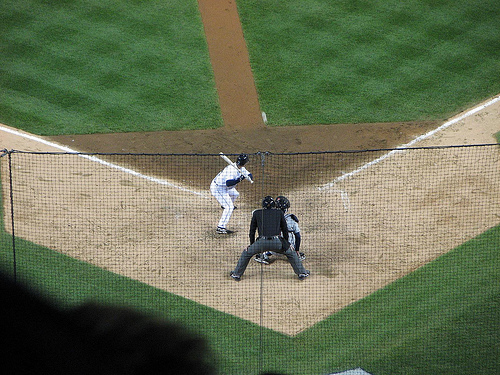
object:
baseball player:
[230, 192, 312, 281]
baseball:
[262, 111, 269, 123]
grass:
[2, 1, 497, 375]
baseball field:
[3, 2, 500, 372]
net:
[2, 147, 499, 372]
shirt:
[215, 160, 250, 184]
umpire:
[231, 194, 311, 282]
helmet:
[236, 152, 251, 164]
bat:
[216, 152, 255, 185]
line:
[2, 124, 204, 203]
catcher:
[256, 195, 307, 262]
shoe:
[216, 225, 228, 236]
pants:
[233, 239, 311, 277]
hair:
[3, 271, 216, 373]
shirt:
[249, 202, 288, 242]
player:
[200, 147, 253, 240]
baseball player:
[209, 145, 256, 235]